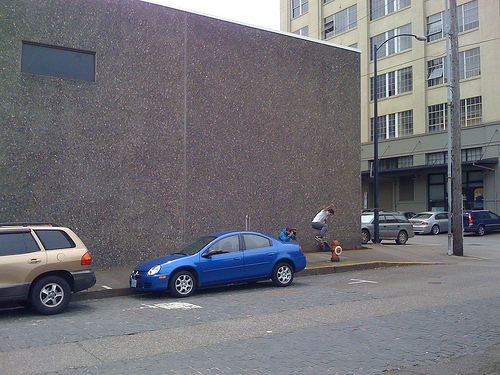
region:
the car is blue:
[185, 154, 330, 368]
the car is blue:
[142, 136, 267, 348]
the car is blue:
[173, 171, 235, 266]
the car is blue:
[185, 211, 282, 371]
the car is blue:
[242, 225, 298, 357]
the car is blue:
[173, 229, 249, 361]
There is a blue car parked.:
[136, 220, 313, 294]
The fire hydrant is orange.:
[324, 238, 347, 263]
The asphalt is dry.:
[85, 300, 445, 360]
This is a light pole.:
[371, 32, 428, 245]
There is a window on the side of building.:
[6, 15, 125, 102]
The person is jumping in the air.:
[310, 198, 335, 250]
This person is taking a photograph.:
[277, 224, 302, 248]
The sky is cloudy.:
[158, 1, 286, 31]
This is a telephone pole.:
[440, 2, 475, 257]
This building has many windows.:
[295, 3, 492, 148]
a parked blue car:
[130, 230, 305, 297]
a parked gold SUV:
[0, 216, 94, 310]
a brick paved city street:
[12, 249, 482, 373]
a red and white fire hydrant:
[330, 241, 341, 261]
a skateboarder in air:
[309, 199, 333, 244]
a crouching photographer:
[275, 223, 297, 248]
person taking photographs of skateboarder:
[275, 199, 337, 258]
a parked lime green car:
[358, 206, 416, 246]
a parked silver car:
[405, 209, 445, 234]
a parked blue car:
[463, 209, 498, 237]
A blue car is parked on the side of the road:
[135, 231, 305, 286]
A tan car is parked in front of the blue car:
[0, 223, 95, 315]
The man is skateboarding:
[307, 202, 334, 253]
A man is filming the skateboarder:
[276, 222, 298, 240]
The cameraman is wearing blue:
[279, 230, 298, 242]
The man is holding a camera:
[292, 229, 298, 234]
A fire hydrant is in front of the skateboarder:
[330, 240, 344, 260]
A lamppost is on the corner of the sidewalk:
[369, 40, 384, 240]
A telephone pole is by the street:
[440, 2, 465, 255]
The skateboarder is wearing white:
[312, 209, 329, 226]